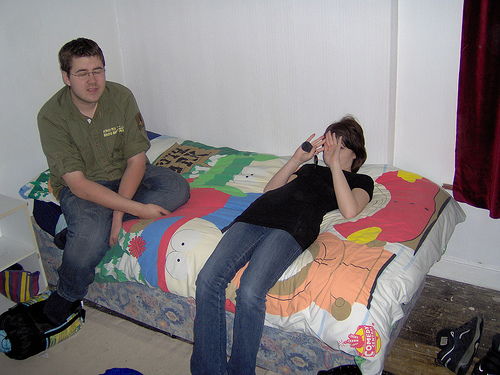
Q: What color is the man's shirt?
A: Green.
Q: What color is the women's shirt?
A: Black.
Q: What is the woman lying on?
A: A bed.